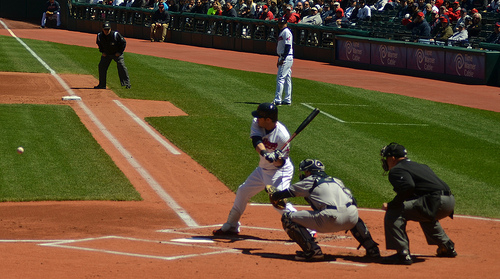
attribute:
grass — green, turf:
[1, 104, 142, 202]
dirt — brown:
[1, 17, 500, 113]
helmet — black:
[252, 102, 279, 122]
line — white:
[1, 20, 199, 228]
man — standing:
[270, 18, 294, 106]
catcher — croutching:
[266, 157, 382, 260]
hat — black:
[101, 20, 112, 31]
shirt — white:
[275, 27, 296, 55]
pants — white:
[276, 54, 295, 104]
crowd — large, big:
[73, 0, 499, 49]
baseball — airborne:
[17, 146, 25, 154]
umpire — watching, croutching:
[380, 142, 457, 265]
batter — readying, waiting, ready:
[211, 101, 294, 236]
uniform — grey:
[284, 174, 376, 252]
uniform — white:
[276, 26, 294, 103]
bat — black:
[282, 106, 321, 150]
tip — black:
[297, 105, 322, 134]